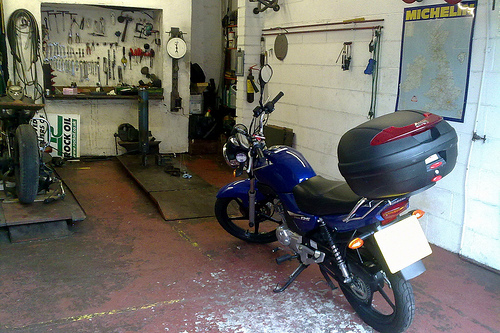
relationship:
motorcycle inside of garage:
[215, 91, 459, 332] [0, 0, 497, 333]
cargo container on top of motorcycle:
[335, 109, 459, 200] [215, 91, 459, 332]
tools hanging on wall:
[40, 3, 163, 98] [0, 0, 187, 152]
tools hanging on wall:
[255, 18, 385, 74] [262, 0, 395, 109]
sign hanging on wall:
[395, 1, 479, 112] [262, 0, 395, 109]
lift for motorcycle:
[116, 151, 215, 215] [215, 91, 459, 332]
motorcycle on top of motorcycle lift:
[215, 91, 459, 332] [116, 151, 216, 219]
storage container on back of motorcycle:
[335, 109, 459, 200] [215, 91, 459, 332]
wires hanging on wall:
[5, 6, 41, 101] [0, 0, 187, 152]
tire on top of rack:
[11, 123, 40, 207] [0, 151, 87, 240]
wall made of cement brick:
[0, 0, 187, 152] [305, 85, 351, 111]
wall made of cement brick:
[262, 0, 395, 109] [305, 85, 351, 111]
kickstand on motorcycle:
[262, 249, 318, 296] [215, 91, 459, 332]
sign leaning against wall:
[33, 113, 80, 163] [0, 0, 187, 152]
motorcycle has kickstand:
[215, 91, 459, 332] [262, 249, 318, 296]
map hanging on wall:
[395, 1, 479, 112] [262, 0, 395, 109]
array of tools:
[41, 9, 156, 83] [40, 3, 163, 98]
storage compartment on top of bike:
[335, 109, 459, 200] [215, 91, 459, 332]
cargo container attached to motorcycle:
[335, 109, 459, 200] [215, 91, 459, 332]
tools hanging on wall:
[255, 18, 385, 120] [262, 0, 395, 109]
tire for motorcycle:
[11, 123, 40, 207] [215, 91, 459, 332]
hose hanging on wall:
[5, 6, 41, 101] [0, 0, 187, 152]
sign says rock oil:
[33, 113, 80, 163] [60, 115, 74, 159]